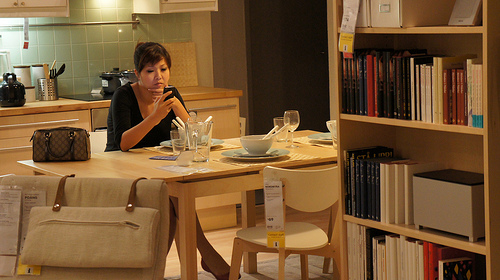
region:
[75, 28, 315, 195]
this is a woman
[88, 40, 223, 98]
the woman is asian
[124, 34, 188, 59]
the woman has black hair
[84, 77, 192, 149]
the shirt is black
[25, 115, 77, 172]
this is a purse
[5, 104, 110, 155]
the purse is gray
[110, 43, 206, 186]
woman on phone at table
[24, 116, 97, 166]
black and grey purse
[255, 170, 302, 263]
tag hanging on chair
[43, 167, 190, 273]
tan organizer hanging off chair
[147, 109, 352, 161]
table ware set for dinner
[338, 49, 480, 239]
tan bookshelf with books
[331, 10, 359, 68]
tag hanging on bookshelf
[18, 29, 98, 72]
mint green tile backsplash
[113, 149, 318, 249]
light brown wooden table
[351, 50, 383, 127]
red books on shelf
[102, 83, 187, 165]
woman wearing black top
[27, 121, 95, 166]
woman with gucci gag on table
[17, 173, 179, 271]
beige cotton bag with leather handles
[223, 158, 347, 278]
wooden chair for sale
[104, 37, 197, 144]
Asian woman using cell phone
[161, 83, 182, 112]
black cell phone being held by woman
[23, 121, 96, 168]
brown Gucci bag on wooden table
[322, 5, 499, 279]
wooden bookshelf for sale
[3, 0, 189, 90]
green ceramic tile backsplash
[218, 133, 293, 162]
white bowl and plate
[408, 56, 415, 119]
white book on tan shelf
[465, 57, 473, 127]
white book on tan shelf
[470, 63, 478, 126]
white book on tan shelf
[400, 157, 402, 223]
white book on tan shelf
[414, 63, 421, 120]
white book on tan shelf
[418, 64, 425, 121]
white book on tan shelf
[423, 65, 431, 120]
white book on tan shelf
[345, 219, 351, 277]
white book on tan shelf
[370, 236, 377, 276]
white book on tan shelf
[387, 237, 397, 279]
white book on tan shelf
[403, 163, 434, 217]
a book in a shelf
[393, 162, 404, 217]
a book in a shelf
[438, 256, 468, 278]
a book in a shelf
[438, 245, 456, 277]
a book in a shelf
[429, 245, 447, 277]
a book in a shelf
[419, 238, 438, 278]
a book in a shelf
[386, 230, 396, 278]
a book in a shelf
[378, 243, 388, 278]
a book in a shelf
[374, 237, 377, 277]
a book in a shelf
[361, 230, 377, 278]
a book in a shelf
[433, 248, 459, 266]
a book in a shelf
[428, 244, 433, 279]
a book in a shelf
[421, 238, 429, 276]
a book in a shelf